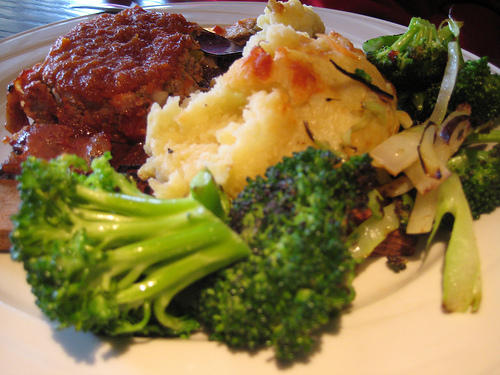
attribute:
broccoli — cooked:
[362, 18, 456, 89]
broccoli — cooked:
[419, 54, 499, 126]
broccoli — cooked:
[442, 142, 499, 219]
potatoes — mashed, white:
[135, 1, 413, 200]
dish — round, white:
[1, 1, 499, 370]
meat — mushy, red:
[6, 5, 258, 195]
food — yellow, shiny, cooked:
[2, 2, 497, 367]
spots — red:
[243, 44, 320, 95]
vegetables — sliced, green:
[347, 43, 487, 319]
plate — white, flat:
[1, 1, 499, 371]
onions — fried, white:
[350, 37, 488, 315]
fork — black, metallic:
[66, 1, 247, 61]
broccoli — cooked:
[15, 149, 253, 346]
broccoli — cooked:
[183, 146, 386, 367]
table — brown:
[0, 1, 499, 71]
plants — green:
[9, 145, 376, 366]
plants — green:
[357, 16, 496, 222]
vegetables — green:
[357, 14, 498, 222]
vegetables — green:
[15, 142, 377, 366]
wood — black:
[2, 1, 500, 69]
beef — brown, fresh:
[1, 7, 262, 201]